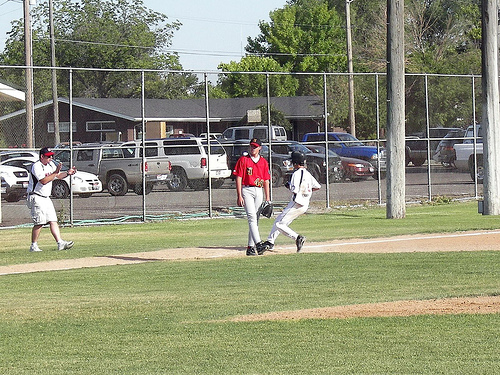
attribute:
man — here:
[25, 145, 79, 251]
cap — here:
[38, 145, 55, 157]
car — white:
[123, 143, 233, 189]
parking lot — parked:
[1, 120, 490, 221]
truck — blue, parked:
[303, 134, 388, 183]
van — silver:
[216, 126, 288, 146]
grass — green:
[21, 285, 198, 373]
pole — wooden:
[382, 1, 410, 222]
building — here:
[5, 98, 357, 149]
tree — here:
[7, 4, 194, 96]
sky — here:
[163, 3, 263, 74]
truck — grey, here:
[55, 141, 170, 194]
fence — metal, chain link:
[0, 59, 481, 227]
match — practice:
[28, 134, 334, 271]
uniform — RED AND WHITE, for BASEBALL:
[234, 152, 270, 242]